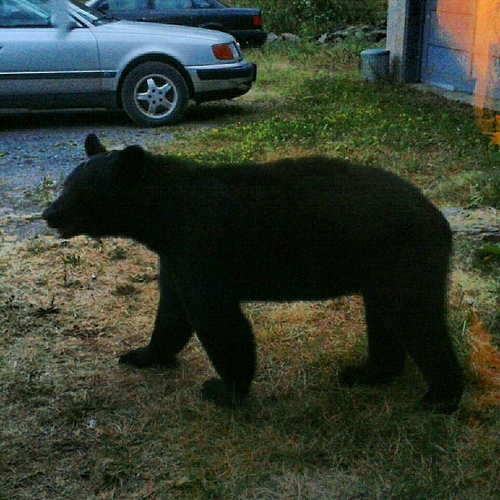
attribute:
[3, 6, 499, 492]
field — here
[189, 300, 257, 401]
leg — here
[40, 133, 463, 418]
bear — black, big, heavy, strong, wild, hungry, large, dark, standing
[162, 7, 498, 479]
grass — here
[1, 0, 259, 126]
car — silver, parked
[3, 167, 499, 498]
patches — green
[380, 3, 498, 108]
garage — grey, shadowed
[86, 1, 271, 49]
car — black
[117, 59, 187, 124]
tire — here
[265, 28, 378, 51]
rocks — present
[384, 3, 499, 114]
wall — lit